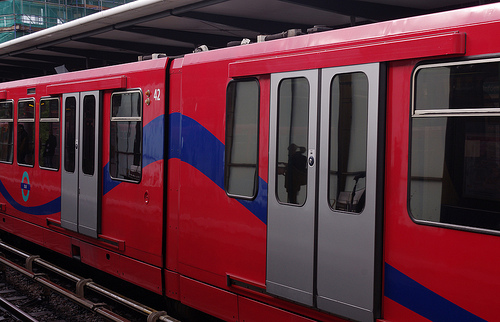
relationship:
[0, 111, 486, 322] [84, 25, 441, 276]
stripe on train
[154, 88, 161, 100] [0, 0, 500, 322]
number on car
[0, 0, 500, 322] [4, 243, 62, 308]
car on track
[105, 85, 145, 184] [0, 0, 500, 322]
window on car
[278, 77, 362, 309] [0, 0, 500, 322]
door on car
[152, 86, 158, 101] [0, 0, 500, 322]
number on car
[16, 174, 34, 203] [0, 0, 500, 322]
logo on car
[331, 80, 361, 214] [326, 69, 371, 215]
reflection on window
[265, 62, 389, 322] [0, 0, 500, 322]
door on side of car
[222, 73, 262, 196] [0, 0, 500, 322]
window on side of car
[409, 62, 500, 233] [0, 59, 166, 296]
window on car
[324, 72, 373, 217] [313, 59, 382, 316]
window on door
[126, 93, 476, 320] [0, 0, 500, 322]
stripe on car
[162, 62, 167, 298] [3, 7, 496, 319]
division between train cars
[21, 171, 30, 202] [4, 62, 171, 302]
logo on side of train car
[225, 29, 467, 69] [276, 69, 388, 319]
bar over door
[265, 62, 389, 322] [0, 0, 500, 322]
door of car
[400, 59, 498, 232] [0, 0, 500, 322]
window on side of car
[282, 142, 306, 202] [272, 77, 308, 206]
reflection in window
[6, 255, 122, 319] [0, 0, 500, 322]
tracks under car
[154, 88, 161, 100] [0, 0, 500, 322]
number on side of car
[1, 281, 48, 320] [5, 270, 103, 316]
railroad on ground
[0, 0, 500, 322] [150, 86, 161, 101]
car has number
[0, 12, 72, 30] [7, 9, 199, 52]
guard rail above canopy